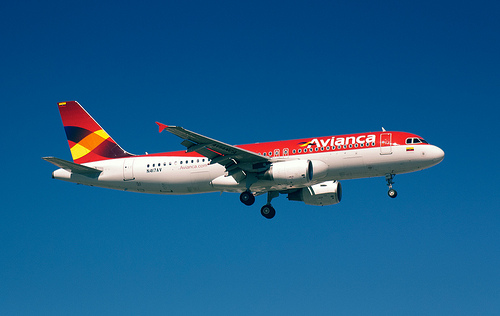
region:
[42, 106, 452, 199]
this is a plane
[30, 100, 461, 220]
the plane is on air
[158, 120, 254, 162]
this is the wing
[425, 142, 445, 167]
the head is streamlined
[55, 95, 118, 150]
this is the tail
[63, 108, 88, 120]
the tail is red in color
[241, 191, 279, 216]
these are the wheels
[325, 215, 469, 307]
the sky is clear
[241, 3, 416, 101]
the sky s blue in color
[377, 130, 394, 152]
the door is closed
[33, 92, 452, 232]
a plane flying through the sky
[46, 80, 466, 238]
an airplane in the sky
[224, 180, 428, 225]
landing gear of the plane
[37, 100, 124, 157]
colorful tail fin of the plane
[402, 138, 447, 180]
white nose of the plane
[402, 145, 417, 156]
flag on the side of the plane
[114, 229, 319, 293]
clear blue skies over the plane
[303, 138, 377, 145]
white lettering on the side of the plane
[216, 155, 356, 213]
twin engines of the plane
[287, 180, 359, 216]
a large jet engine on a plane.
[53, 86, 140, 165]
a large wing on a plane.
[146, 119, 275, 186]
a large wing on a jet.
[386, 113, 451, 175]
a cock pit on a jet.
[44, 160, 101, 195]
a large engine on a jet.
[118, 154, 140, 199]
a door on a jet.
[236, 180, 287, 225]
landing gear on a plane.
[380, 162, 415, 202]
large landing gear.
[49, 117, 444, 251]
a fusel lodge on of a jet.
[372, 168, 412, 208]
front end landing gear.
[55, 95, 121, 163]
Red, blue, and yellow tail on the plane.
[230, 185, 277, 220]
Landing gear on the plane.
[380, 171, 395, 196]
Front wheels on the plane.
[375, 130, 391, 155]
Door on the side of the plane.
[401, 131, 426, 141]
Front windows on the plane.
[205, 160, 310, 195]
Engine on the airplane.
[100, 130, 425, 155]
Red stripe top on the plane.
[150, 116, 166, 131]
Red tip on the wing.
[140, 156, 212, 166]
Windows on the side of the plane.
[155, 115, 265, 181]
Wing on the airplane.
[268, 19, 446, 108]
this is the sky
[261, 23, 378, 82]
the sky is blue n color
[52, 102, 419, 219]
this is a jet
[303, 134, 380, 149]
this is a writing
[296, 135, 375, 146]
the writing is in white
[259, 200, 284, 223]
this is the wheel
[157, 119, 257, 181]
this is the wing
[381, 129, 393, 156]
this is the door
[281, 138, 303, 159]
the jet is red and white in color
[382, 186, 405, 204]
this is the front wheel